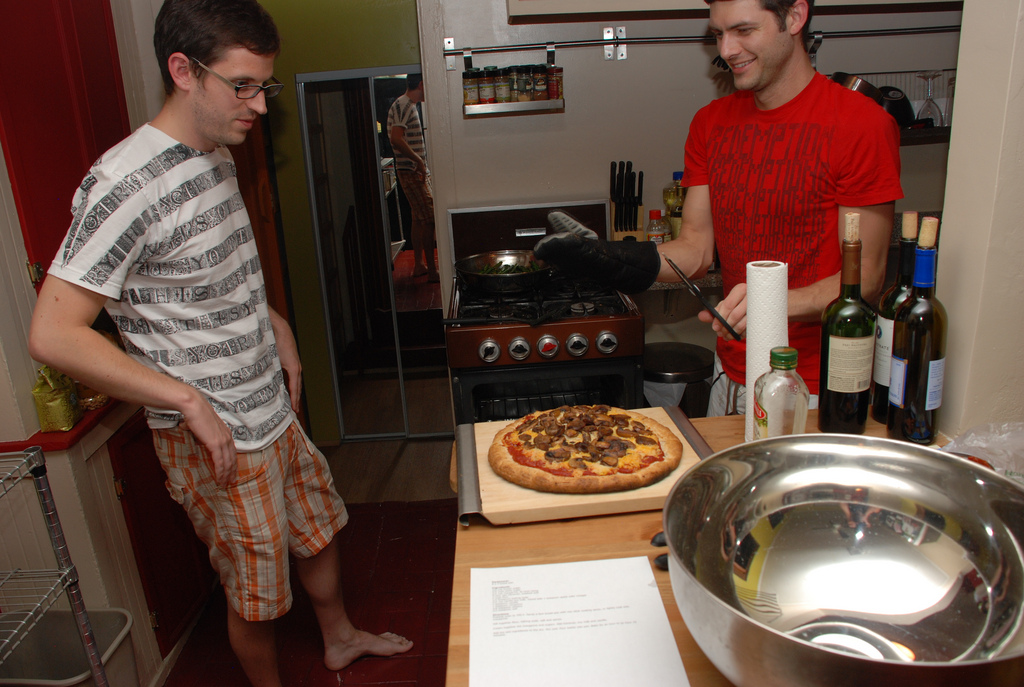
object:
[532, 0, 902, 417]
man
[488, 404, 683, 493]
pizza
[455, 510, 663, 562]
table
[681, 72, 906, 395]
shirt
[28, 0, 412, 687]
guy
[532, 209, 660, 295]
mitt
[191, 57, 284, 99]
glasses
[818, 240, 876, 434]
bottle